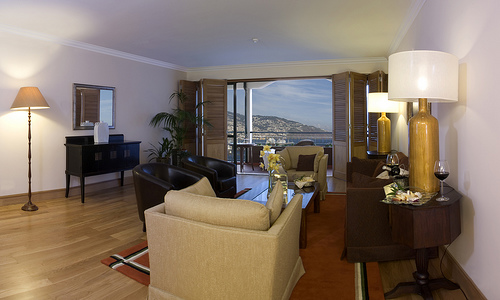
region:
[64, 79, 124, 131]
mirror on the wall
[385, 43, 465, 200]
a desk lamp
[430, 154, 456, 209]
glass of wine on a table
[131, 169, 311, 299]
a small one person couch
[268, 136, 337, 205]
couch with a cushion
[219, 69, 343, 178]
view from the balcony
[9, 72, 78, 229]
a tall lamp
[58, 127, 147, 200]
a four legged wooden desk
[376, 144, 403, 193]
glass of wine on table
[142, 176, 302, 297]
Back of a tan chair.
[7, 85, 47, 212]
Lamp with a tan shade.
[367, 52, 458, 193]
Two gold colored lamps with white shades.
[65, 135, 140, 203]
Brown wooden stand against the wall.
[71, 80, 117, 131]
A framed mirror above the stand.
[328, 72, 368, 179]
Sliding shutters on a glass door.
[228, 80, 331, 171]
A lake view from the patio.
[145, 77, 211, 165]
A tall plant next to the glass door.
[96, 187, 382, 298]
An orange rug on the flood.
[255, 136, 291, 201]
Yellow flowers in a clear vase.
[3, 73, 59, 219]
a floor lamp is in the room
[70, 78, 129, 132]
a mirror hangs on the wall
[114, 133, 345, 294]
four sitting chairs are in the room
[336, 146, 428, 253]
a sofa is up against the wall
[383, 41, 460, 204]
a lamp is on the table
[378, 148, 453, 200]
two glasses of wine are out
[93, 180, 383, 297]
an area rug in in the room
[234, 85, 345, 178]
the door to the patio area is open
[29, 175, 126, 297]
the floor in the room is made up of hardwood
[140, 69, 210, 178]
a small tree is in the corner of the room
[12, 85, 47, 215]
tall floor lamp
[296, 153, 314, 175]
dark throw pillow on the chair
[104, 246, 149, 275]
corner stripes on the rug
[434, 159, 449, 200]
glass of red wine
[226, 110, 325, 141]
mountains are in the view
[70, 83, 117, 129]
framed mirror on the wall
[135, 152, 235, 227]
pair of leather chairs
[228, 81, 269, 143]
patio frame is white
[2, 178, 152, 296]
hard wood flooring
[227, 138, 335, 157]
body of water outside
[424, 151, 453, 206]
a glass of wine by the lamp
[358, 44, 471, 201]
a set of large lamps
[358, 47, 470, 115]
a set of white lamp shades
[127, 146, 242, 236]
a set of black leather chairs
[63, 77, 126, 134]
a large mirror on the wall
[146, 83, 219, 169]
a house plant by the door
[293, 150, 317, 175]
a dark brown pillow in the chair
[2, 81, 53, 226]
a tall lamp on the floor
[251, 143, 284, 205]
a yellow flower on the table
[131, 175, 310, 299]
a tan chair on the rug